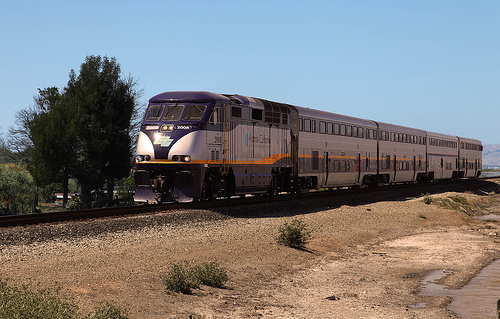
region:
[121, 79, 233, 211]
front part of the train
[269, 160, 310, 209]
wheel of the train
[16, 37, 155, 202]
a long green tree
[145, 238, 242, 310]
a part of the trees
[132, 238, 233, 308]
trees in the sand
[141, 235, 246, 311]
trees in the ground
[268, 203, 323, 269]
a tree near the train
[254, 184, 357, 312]
a tree near the track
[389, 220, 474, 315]
a small watery sand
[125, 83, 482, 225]
a train in the track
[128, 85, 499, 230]
A passenger train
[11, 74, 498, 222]
The train is on tracks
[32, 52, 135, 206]
Several trees by the tracks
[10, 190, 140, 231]
The tracks are made of steel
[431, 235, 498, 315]
Small pool of water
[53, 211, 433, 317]
The ground is covered in dirt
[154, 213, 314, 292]
Small green bushes in the dirt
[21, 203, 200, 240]
A bunch of rocks near the tracks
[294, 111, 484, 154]
Windows on the side of the train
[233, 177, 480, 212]
Train casting a shadow on the ground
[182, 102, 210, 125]
window on a blue and silver train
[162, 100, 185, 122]
window on a blue and silver train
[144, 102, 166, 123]
window on a blue and silver train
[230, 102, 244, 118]
window on a blue and silver train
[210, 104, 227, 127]
window on a blue and silver train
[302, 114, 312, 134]
window on a blue and silver train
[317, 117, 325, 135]
window on a blue and silver train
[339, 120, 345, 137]
window on a blue and silver train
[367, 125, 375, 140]
window on a blue and silver train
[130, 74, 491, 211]
blue and silver train on the tracks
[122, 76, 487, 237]
a silver and black train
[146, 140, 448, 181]
a yellow stripe on the train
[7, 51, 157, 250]
a tree on the side of train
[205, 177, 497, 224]
a shadow cast by train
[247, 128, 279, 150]
black letters on side of train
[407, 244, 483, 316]
a puddle on the ground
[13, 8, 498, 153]
a clear blue sky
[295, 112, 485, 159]
several windows for the passengers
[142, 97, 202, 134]
three windows on the front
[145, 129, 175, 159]
white letters on the front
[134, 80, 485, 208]
long passenger train on tracks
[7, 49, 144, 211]
green trees beside tracks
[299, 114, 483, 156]
windows on side of train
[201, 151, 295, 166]
orange line on train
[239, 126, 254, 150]
blue icon on side of train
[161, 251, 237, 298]
green bushes on side of rail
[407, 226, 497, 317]
water puddle on side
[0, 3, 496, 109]
clear blue skies over train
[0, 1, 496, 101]
cloudless blue sky over train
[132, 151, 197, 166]
lights on front of train